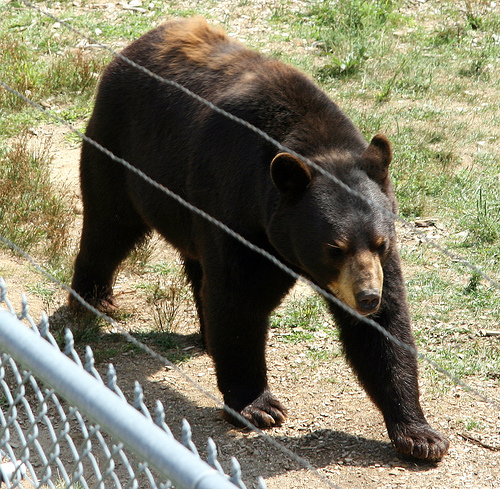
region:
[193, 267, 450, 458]
The front legs of the bear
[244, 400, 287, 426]
The claws of the bear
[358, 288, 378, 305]
The nose of the bear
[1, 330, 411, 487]
A shadow on the ground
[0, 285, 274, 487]
A fence near the bear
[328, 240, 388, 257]
The eyes of the bear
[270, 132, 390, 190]
The ears of the bear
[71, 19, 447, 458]
A bear on the ground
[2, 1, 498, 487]
Wires above the fence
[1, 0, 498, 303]
Grass beneath the bear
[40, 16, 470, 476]
The bear is roaming around freely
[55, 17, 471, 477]
The bear is looking for open garbage cans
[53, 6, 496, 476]
The bear is hunting for small animals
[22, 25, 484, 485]
The bear is outside someone's property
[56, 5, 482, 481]
The bear is walking by a fence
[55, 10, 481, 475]
The bear is a big male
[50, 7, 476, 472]
The bear is a brown bear species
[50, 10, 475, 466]
The bear has long sharp teeth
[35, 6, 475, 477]
The bear has powerful front paws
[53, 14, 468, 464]
The bear has a great sense of smell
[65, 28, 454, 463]
brown bear behind a fence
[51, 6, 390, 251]
wire across the top of the fence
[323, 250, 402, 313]
light brown nose on the bear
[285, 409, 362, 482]
dirt ground under the bear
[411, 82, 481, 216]
patchy green grass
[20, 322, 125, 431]
metal pipe of the fence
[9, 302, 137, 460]
chain link fence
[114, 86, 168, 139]
brown fur on the bear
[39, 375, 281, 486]
shadow on the ground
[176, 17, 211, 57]
light tufts of fur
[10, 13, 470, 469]
The bear is hunting for food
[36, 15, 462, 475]
The bear is looking for a meal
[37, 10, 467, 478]
The bear is hunting small animals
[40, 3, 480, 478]
The bear is looking for garbage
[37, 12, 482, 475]
The bear is on someone's property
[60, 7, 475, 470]
The bear is outside someone's fence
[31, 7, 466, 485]
The bear is looking for a mate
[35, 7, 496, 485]
The bear has big sharp teeth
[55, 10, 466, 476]
The bear is fierce and dangerous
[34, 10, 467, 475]
The bear is not in captivity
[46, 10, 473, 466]
The bear is looking very angry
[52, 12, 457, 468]
The bear is slowly walking around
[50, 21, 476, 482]
The bear is looking for food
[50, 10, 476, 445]
The bear is watching for danger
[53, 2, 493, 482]
The bear is hunting other animals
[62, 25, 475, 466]
The bear is a big female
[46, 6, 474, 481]
The bear is out in the daytime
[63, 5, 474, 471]
The bear is looking for garbage cans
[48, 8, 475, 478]
The bear is enjoying the day